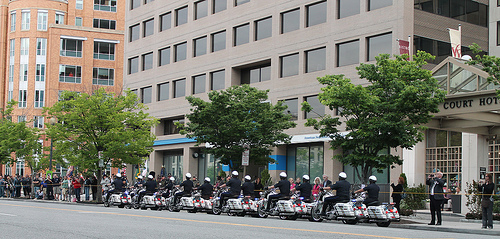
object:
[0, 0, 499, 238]
picture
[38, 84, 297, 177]
trees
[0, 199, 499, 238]
street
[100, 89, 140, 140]
leaves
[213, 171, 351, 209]
police officers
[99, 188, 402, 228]
motorcycles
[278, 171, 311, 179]
helmets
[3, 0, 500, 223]
buildings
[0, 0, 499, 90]
background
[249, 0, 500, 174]
building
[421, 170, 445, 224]
man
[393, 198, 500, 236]
sidewalk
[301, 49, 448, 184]
tree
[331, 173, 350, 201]
man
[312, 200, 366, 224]
motorcycle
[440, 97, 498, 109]
letters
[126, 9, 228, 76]
windows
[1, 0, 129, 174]
building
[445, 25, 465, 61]
banner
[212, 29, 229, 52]
window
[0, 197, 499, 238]
road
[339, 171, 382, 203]
motorists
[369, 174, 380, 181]
helmet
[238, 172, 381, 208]
people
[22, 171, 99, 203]
people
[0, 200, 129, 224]
lines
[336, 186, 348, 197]
black